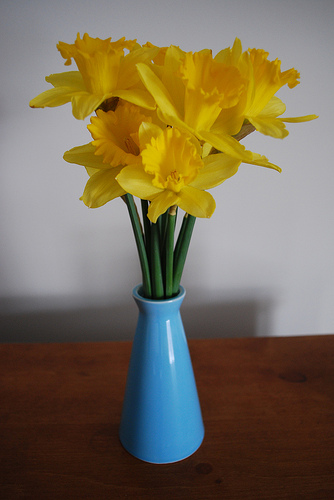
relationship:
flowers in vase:
[39, 31, 297, 225] [117, 278, 206, 468]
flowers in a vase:
[39, 31, 297, 225] [117, 278, 206, 468]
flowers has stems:
[39, 31, 297, 225] [126, 209, 188, 299]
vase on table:
[117, 278, 206, 468] [25, 354, 309, 455]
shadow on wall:
[0, 254, 147, 338] [9, 112, 82, 306]